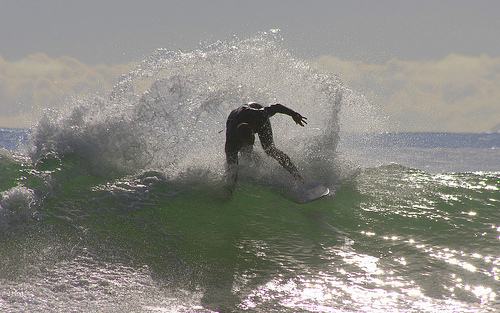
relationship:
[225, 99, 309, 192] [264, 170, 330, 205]
person on surfboard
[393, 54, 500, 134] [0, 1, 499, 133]
cloud in sky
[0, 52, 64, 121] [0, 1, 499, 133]
cloud in sky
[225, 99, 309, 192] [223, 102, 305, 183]
person wearing wetsuit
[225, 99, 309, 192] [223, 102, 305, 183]
person in wetsuit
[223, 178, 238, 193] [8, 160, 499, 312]
hand in water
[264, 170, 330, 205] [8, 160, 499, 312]
surfboard in water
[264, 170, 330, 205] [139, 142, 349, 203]
surfboard riding wave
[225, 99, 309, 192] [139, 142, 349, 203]
person riding wave